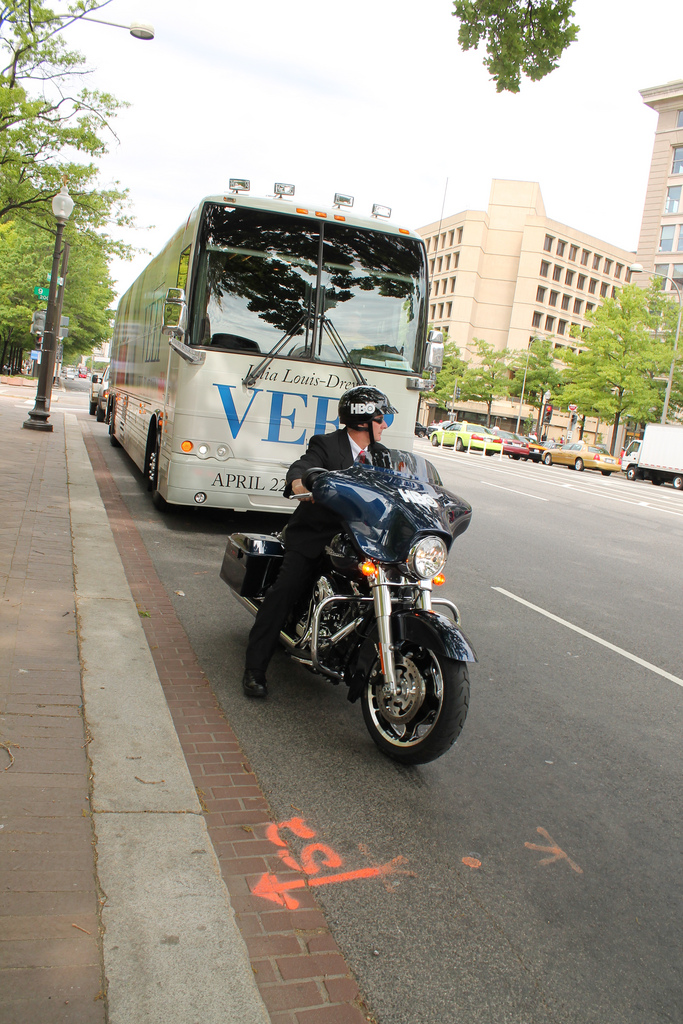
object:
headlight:
[404, 532, 449, 579]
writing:
[212, 381, 266, 449]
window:
[531, 307, 543, 327]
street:
[61, 410, 676, 1020]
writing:
[262, 810, 315, 848]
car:
[428, 418, 505, 458]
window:
[655, 224, 677, 256]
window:
[589, 252, 601, 269]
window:
[453, 225, 464, 242]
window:
[573, 298, 584, 314]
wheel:
[357, 616, 474, 767]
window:
[561, 266, 576, 293]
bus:
[102, 170, 440, 535]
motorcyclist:
[214, 384, 478, 767]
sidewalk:
[5, 365, 281, 1012]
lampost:
[19, 181, 78, 438]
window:
[559, 291, 575, 307]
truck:
[623, 411, 682, 499]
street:
[449, 468, 682, 1021]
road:
[387, 433, 681, 704]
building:
[412, 176, 642, 458]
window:
[539, 233, 555, 253]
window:
[556, 238, 568, 257]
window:
[540, 258, 551, 275]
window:
[533, 284, 546, 303]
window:
[601, 257, 614, 276]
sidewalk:
[2, 417, 185, 1003]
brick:
[169, 675, 210, 692]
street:
[432, 433, 675, 787]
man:
[228, 377, 422, 713]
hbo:
[349, 400, 376, 416]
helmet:
[336, 386, 398, 435]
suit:
[240, 427, 405, 677]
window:
[570, 266, 592, 294]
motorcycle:
[215, 447, 482, 770]